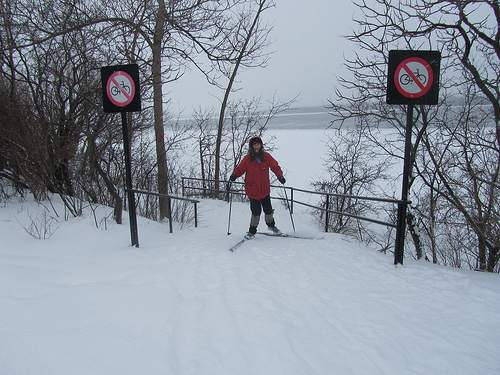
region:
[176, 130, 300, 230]
This is a man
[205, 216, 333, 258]
These are skiis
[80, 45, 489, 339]
These are signs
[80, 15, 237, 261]
The signs say no bikes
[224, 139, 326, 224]
This is a red coat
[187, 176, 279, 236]
These are two poles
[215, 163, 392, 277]
The poles are metal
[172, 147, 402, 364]
There are two skiis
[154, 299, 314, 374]
There is snow on the ground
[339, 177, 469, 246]
There are no leaves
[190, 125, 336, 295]
A skier standing in snow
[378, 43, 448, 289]
a sign that says no bikes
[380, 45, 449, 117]
a black square sign with red and white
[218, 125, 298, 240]
a red jacket and black pants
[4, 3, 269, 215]
trees without any leaves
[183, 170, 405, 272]
a black metal railing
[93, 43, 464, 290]
two poles with signs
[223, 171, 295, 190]
black gloves on hands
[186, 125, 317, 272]
a skier holding two poles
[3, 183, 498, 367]
lots of snow on the ground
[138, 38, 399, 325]
woman on snowy pathway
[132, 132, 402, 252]
low railing on sides of skier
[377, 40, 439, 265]
square sign on dark pole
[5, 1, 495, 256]
bare branches behind poles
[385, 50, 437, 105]
red slash across image of bicycle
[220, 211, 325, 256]
skis at perpendicular angle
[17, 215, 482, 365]
tracks and footprints in snow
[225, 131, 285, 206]
skier in long red jacket with hood pulled up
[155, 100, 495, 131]
low land formation at horizon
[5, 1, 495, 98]
clear gray sky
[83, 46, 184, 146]
Black sign connected to pole.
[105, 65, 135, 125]
Black bike on sign.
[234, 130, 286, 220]
Person wearing red coat.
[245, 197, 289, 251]
Person wearing black pants.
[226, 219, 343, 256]
Person wearing skis on feet.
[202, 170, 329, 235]
Person holding 2 ski poles.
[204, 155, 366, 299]
Person standing in front of railing.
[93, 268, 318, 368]
Snow covering ground.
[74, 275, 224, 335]
Snow on ground is white.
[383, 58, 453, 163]
Black sign on black pole.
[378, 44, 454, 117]
Red and white sign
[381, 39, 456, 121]
No bicycle sign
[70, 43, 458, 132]
Two red and white signs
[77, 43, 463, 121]
Two no bicycle signs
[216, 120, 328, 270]
A person in a red jacket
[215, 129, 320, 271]
A person on skis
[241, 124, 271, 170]
A person wearing a winter hat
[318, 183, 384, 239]
A silver metal railing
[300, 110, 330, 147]
A frozen body of water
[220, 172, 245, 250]
Someone holding a ski pole